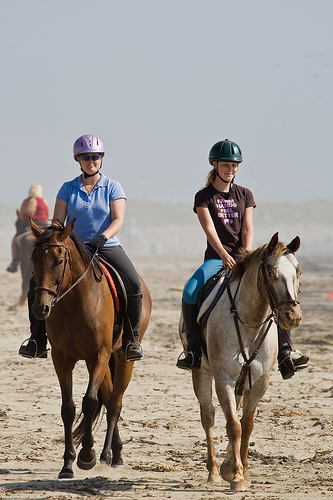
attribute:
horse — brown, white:
[176, 232, 306, 494]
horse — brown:
[24, 218, 155, 479]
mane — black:
[36, 220, 104, 267]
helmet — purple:
[67, 133, 107, 165]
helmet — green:
[208, 138, 246, 164]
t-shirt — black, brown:
[192, 182, 257, 259]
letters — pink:
[212, 195, 241, 226]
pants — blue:
[182, 258, 225, 307]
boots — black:
[173, 299, 311, 379]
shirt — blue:
[55, 173, 126, 248]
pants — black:
[25, 243, 144, 335]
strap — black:
[79, 164, 105, 180]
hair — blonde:
[205, 167, 219, 188]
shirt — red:
[17, 197, 51, 226]